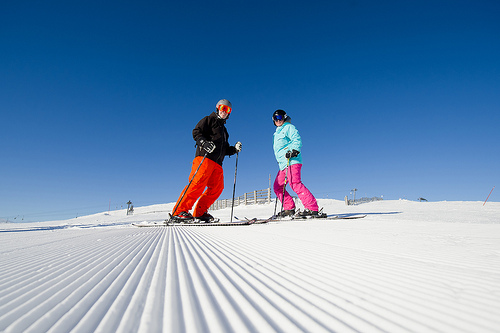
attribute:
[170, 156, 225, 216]
pants — orange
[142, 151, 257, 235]
pants — warm, pink, winter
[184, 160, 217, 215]
pants — orange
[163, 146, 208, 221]
ski pole — black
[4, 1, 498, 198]
sky — blue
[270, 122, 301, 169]
coat — light, blue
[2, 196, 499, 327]
ground — snowy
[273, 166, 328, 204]
pants — pink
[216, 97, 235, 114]
helmet — protective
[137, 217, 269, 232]
skis — nice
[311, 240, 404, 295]
snow — white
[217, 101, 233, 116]
goggles — bright, orange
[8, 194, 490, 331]
snow — white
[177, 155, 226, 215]
ski pants — red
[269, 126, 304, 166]
coat — blue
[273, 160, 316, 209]
pants — pink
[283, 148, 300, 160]
gloves — Black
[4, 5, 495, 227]
sky — blue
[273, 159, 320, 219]
pants — pink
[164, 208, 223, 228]
equipment — ski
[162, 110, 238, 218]
clothing — black, orange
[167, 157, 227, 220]
pants — orange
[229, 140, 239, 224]
pole — ski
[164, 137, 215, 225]
pole — ski